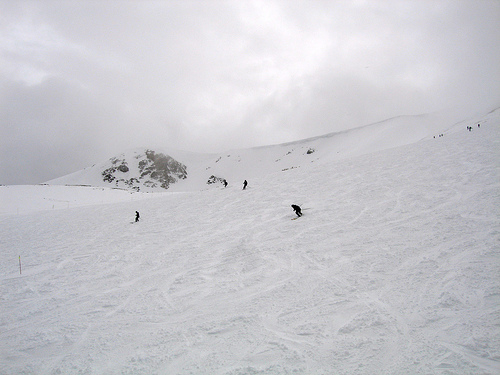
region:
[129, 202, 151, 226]
person skiing down white snow covered mountain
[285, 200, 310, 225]
person skiing down white snow covered mountain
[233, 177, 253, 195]
person skiing down white snow covered mountain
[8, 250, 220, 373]
white snow covered mountain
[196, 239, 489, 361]
white snow covered mountain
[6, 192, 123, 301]
white snow covered mountain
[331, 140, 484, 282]
white snow covered mountain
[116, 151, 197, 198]
white snow covered mountain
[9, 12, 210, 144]
gray and white clouds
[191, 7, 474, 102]
gray and white clouds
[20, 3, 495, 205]
a cloudy day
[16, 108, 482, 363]
a snowy scene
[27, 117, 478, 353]
people are skiing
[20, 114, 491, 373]
people ski down the mountain side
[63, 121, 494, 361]
many people have skied down this mountain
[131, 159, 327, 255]
the four skiers are wearing black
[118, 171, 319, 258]
the people are using skis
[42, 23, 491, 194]
the sky is very cloudy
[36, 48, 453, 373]
a winter time scene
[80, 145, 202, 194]
a rocky outcrop on the mountain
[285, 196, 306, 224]
Person wearing black cloths.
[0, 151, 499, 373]
Snow on the field.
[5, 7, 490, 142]
Day is cloudy.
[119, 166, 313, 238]
Skiers going down the hill.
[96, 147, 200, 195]
Part of the mountain in not covered with snow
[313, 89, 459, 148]
Mountain is covered with snow.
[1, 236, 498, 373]
Snow trucks on the snow.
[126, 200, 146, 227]
Person in front of other people.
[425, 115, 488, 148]
Several people on the hill.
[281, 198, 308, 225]
Person is crouched.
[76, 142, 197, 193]
A rocky mountain top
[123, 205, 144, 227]
a person snowboarding on a mountain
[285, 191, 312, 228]
a person skiing on a mountain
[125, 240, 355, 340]
snow-covered mountain trail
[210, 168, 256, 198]
two skiiers in the distance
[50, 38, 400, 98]
cloudy overcast sky line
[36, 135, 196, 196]
snow-covered mountain top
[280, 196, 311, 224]
a person participating in sport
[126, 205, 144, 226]
A person exercising outdoors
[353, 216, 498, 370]
snow with ski paths carved in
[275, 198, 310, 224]
skier in the snowy mountains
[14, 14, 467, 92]
cloudy grey sky in the background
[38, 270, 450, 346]
white snow on the ground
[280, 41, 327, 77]
sunlight peeking out from behind the clouds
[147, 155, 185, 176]
part of mountain not covered in snow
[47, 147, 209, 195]
hill on a mountain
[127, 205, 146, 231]
skier going down a hill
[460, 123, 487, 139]
group of three skiers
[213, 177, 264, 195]
two skiers in the distance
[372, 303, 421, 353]
track in the snow from skiis